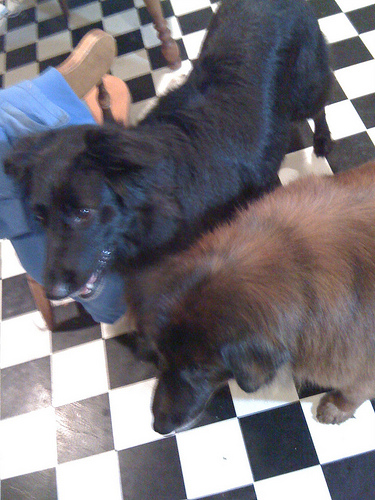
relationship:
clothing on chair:
[5, 68, 116, 288] [3, 25, 137, 335]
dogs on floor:
[13, 23, 373, 430] [6, 4, 369, 499]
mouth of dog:
[70, 265, 97, 299] [11, 5, 315, 342]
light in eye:
[83, 211, 86, 212] [68, 203, 92, 223]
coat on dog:
[166, 27, 284, 185] [11, 5, 315, 342]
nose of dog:
[42, 282, 73, 302] [11, 5, 315, 342]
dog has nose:
[11, 5, 315, 342] [42, 282, 73, 302]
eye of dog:
[68, 203, 92, 223] [11, 5, 315, 342]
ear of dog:
[80, 123, 168, 211] [11, 5, 315, 342]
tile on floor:
[45, 393, 120, 462] [6, 4, 369, 499]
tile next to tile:
[45, 393, 120, 462] [47, 335, 124, 405]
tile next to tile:
[47, 335, 124, 405] [45, 393, 120, 462]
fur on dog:
[138, 27, 256, 150] [11, 5, 315, 342]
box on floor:
[45, 393, 120, 462] [6, 4, 369, 499]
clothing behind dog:
[5, 68, 116, 288] [11, 5, 315, 342]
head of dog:
[5, 118, 155, 307] [11, 5, 315, 342]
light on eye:
[83, 211, 86, 212] [68, 203, 92, 223]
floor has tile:
[2, 336, 373, 498] [45, 393, 120, 462]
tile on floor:
[45, 393, 120, 462] [0, 1, 141, 499]